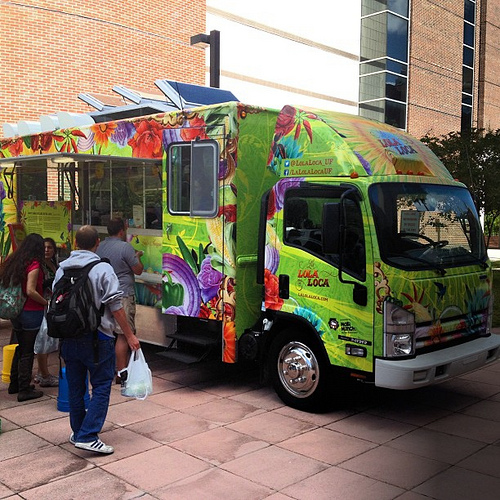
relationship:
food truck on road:
[1, 77, 499, 414] [2, 323, 500, 497]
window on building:
[461, 18, 478, 52] [2, 0, 500, 249]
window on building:
[357, 13, 410, 62] [2, 0, 500, 249]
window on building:
[357, 56, 410, 80] [2, 0, 500, 249]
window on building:
[358, 75, 410, 104] [2, 0, 500, 249]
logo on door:
[297, 268, 333, 291] [263, 179, 378, 377]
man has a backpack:
[44, 223, 142, 458] [44, 256, 116, 365]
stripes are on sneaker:
[87, 439, 106, 453] [75, 439, 115, 458]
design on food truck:
[94, 121, 119, 150] [1, 77, 499, 414]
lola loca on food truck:
[297, 268, 333, 291] [1, 77, 499, 414]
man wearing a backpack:
[44, 223, 142, 458] [44, 256, 116, 365]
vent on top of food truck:
[75, 90, 116, 115] [1, 77, 499, 414]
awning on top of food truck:
[2, 153, 166, 176] [1, 77, 499, 414]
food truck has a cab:
[1, 77, 499, 414] [264, 103, 499, 393]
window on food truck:
[164, 138, 224, 220] [1, 77, 499, 414]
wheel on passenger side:
[267, 322, 336, 416] [273, 171, 374, 373]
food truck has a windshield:
[1, 77, 499, 414] [369, 178, 489, 273]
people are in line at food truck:
[2, 214, 145, 461] [1, 77, 499, 414]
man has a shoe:
[44, 223, 142, 458] [75, 439, 115, 458]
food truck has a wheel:
[1, 77, 499, 414] [267, 322, 336, 416]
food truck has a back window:
[1, 77, 499, 414] [18, 161, 78, 206]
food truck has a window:
[1, 77, 499, 414] [284, 184, 366, 282]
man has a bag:
[44, 223, 142, 458] [123, 349, 157, 403]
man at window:
[99, 217, 146, 387] [83, 158, 163, 239]